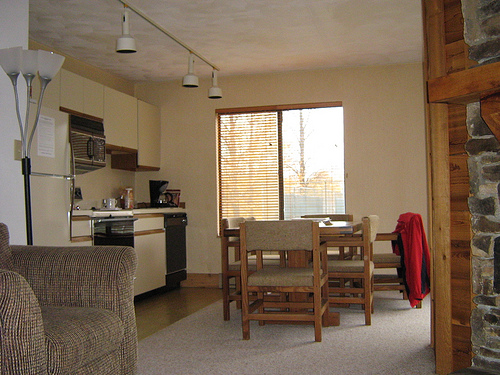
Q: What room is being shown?
A: A kitchen.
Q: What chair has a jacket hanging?
A: Chair on the right.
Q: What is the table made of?
A: Wood.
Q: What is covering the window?
A: Shade.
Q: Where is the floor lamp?
A: On the left.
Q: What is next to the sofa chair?
A: A floor lamp.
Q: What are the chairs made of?
A: Wood.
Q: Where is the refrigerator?
A: Behind the lamp.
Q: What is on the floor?
A: Carpeting.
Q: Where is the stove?
A: Corner back wall.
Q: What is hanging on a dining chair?
A: A red jacket.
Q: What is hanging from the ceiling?
A: Lights.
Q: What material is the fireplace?
A: Brick.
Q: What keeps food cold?
A: The refrigerator.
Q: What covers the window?
A: Blinds.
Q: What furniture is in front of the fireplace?
A: An armchair.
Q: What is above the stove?
A: A microwave.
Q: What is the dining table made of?
A: Wood.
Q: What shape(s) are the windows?
A: Rectangular.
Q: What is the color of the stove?
A: Black.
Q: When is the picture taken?
A: Daytime.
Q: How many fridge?
A: 1.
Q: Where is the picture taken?
A: In a living room.